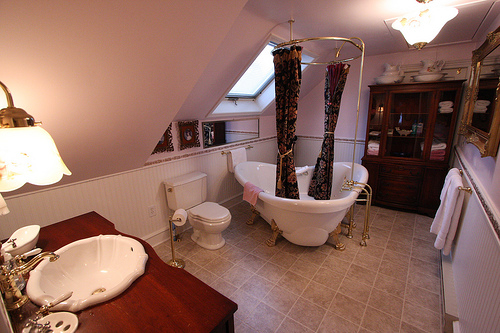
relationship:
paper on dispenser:
[166, 208, 186, 229] [161, 212, 182, 268]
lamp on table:
[0, 80, 73, 194] [1, 206, 21, 331]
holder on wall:
[219, 137, 253, 160] [213, 137, 265, 175]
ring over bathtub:
[273, 30, 367, 50] [231, 159, 370, 251]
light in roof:
[226, 46, 312, 105] [162, 10, 318, 142]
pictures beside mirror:
[155, 106, 229, 162] [461, 47, 499, 145]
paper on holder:
[166, 208, 186, 229] [164, 215, 185, 269]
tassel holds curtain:
[266, 26, 369, 60] [300, 62, 356, 201]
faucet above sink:
[6, 243, 60, 268] [19, 235, 154, 315]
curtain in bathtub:
[300, 62, 356, 201] [231, 159, 370, 251]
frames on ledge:
[158, 114, 228, 152] [141, 144, 228, 167]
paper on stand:
[166, 208, 186, 229] [162, 206, 176, 271]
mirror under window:
[461, 47, 499, 145] [205, 119, 259, 145]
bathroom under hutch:
[0, 0, 497, 331] [360, 83, 469, 217]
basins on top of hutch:
[374, 61, 444, 83] [360, 83, 469, 217]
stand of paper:
[165, 217, 183, 268] [166, 208, 186, 229]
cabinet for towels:
[356, 78, 466, 219] [430, 138, 446, 161]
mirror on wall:
[461, 47, 499, 145] [457, 140, 497, 221]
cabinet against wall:
[361, 82, 461, 217] [370, 43, 464, 63]